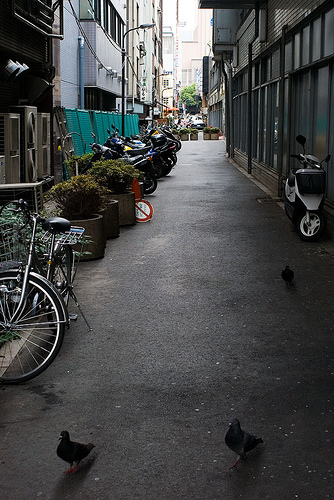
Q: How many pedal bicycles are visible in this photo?
A: Two.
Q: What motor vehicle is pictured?
A: Moped.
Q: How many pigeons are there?
A: Three.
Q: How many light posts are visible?
A: Three.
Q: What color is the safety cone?
A: Orange.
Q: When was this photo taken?
A: Day time.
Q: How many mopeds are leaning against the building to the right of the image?
A: One.